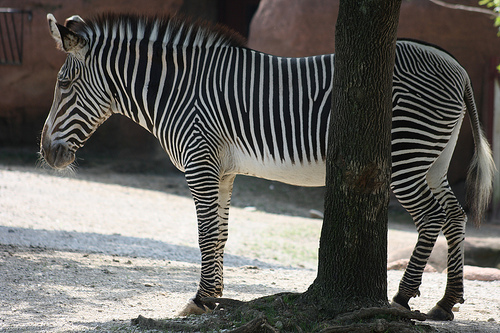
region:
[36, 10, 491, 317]
large black and white zebra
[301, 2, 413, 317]
large tree in front of zebra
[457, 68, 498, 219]
zebra has bushy tail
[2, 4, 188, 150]
building behind zebra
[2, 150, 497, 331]
ground is dirt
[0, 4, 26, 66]
metal attachment to building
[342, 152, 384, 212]
tree has holes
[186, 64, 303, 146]
Black and white stripes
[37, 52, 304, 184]
Black and white stripes of a zebra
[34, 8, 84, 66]
Ear of a zebra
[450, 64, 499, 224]
Tail of a zebra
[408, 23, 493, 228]
Rear of a zebra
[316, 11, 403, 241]
Trunk of a tree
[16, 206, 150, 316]
Shadows on the ground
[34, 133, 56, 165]
Nose of a zebra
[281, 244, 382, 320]
Bottom of a tree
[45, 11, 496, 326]
Zebra standing by a tree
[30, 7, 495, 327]
Zebra looking at the ground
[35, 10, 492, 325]
Zebra with black and white stripes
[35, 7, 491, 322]
Zebra stands out of the sun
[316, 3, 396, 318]
A brown tree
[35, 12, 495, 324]
Zebra with a white belly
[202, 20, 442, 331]
Tree with roots on the ground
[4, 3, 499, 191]
A wall of rocks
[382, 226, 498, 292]
A hole in the ground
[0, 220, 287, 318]
Shadow of a tree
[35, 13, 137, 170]
Head of a zebra with sad looking face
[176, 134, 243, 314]
Front legs of zebra displaying stripes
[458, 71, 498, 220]
Tail of zebra displaying fluffy end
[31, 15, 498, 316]
Zebra standing behind a tree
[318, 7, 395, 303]
Medium thickness hardwood tree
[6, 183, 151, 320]
Sandy and loamy ground structure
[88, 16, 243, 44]
Mane of zebra displaying fringed stripes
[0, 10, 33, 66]
Metal container hanging on a wall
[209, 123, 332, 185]
Belly of zebra with noted absence of stripes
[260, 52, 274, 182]
black stripe on animal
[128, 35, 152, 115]
black stripe on animal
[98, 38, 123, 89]
black stripe on animal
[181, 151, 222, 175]
black stripe on animal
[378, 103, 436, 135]
black stripe on animal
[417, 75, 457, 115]
black stripe on animal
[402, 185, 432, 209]
black stripe on animal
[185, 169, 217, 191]
black stripe on animal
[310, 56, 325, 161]
black stripe on animal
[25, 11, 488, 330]
this is a zebra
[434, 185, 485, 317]
the foot of a zebra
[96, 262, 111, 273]
A rock on the ground.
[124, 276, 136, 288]
A rock on the ground.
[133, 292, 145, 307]
A rock on the ground.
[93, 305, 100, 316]
A rock on the ground.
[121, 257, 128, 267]
A rock on the ground.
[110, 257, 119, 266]
A rock on the ground.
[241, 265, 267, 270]
A rock on the ground.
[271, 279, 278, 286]
A rock on the ground.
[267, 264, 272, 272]
A rock on the ground.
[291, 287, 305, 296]
A rock on the ground.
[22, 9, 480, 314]
black and white striped zebra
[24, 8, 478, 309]
black and white striped zebra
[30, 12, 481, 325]
black and white striped zebra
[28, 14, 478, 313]
striped zebra